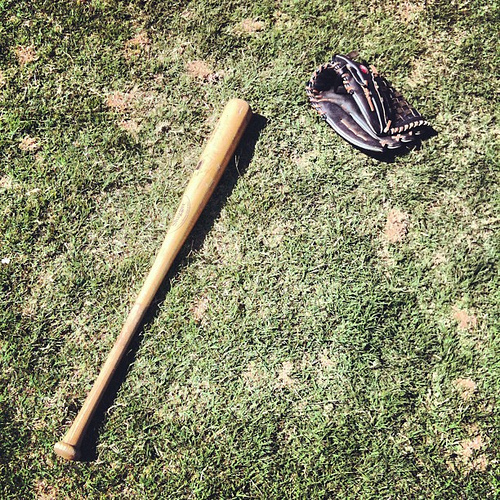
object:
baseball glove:
[302, 51, 442, 159]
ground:
[4, 1, 500, 499]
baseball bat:
[54, 98, 253, 463]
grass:
[236, 113, 388, 323]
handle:
[43, 319, 154, 465]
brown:
[104, 82, 143, 126]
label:
[358, 59, 370, 76]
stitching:
[382, 117, 434, 133]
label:
[168, 197, 189, 232]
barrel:
[163, 89, 255, 239]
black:
[177, 214, 182, 218]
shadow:
[81, 113, 267, 458]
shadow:
[355, 126, 443, 164]